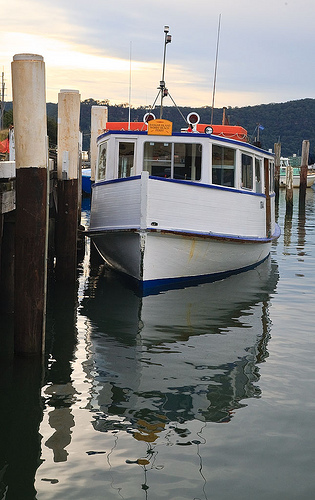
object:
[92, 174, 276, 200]
trim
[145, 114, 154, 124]
light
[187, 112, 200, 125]
light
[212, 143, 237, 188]
window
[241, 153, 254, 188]
window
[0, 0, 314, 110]
sky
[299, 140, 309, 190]
post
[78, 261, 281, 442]
reflection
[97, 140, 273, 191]
windows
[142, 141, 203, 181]
window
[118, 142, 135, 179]
window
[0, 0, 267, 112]
light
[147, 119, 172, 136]
sign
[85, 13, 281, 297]
boat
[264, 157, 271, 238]
door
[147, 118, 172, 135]
tag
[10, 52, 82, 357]
wood poles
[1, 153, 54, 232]
wooden dock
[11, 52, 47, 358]
post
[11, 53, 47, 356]
pillar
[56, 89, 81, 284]
pillar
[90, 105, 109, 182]
pillar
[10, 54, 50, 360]
dock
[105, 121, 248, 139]
objects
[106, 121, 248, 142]
rafts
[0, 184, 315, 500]
water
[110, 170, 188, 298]
bow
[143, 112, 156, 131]
horn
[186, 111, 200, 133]
horn